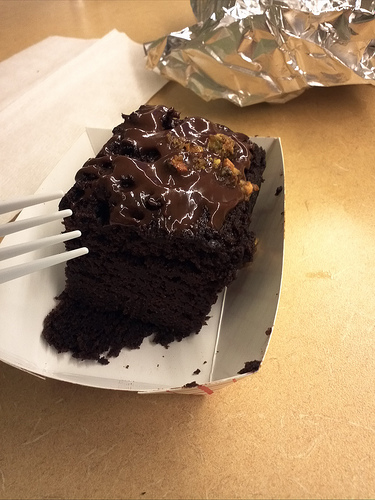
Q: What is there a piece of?
A: Chocolate cake.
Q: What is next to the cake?
A: A fork.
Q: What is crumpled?
A: Tin foil.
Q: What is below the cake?
A: Table.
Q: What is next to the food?
A: White napkin.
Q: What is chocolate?
A: The cake.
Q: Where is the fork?
A: Next to cake.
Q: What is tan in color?
A: Surface of the table.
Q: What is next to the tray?
A: White napkin.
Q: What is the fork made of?
A: Plastic.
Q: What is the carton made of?
A: Poster board.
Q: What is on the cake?
A: Brown frosting.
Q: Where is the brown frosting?
A: On the cake.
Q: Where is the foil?
A: Behind the carton.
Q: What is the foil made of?
A: Aluminum.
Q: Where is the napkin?
A: Next to the foil.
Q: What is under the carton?
A: The table.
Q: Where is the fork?
A: Next to the cake.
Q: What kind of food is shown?
A: Brownie.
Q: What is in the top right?
A: Aluminum foil.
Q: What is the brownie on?
A: A paper plate.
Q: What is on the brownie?
A: Hot fudge and nuts.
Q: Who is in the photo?
A: Nobody is.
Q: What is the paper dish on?
A: A table.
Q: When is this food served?
A: Dessert time.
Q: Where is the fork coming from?
A: The left.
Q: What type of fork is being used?
A: Plastic.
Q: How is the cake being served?
A: In a disposable paper dish.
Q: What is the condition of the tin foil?
A: Crumpled into a ball.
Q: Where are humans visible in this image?
A: Nowhere.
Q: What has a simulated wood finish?
A: The table beneath the cake.